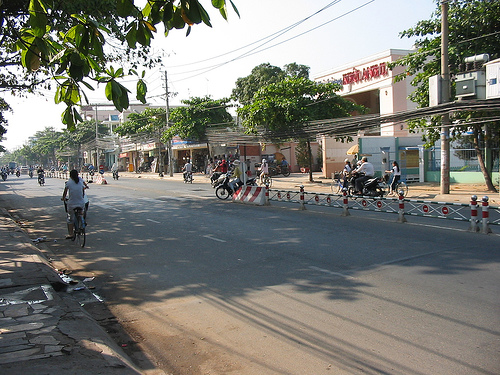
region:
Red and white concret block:
[235, 186, 266, 203]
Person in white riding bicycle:
[62, 169, 90, 241]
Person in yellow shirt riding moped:
[217, 159, 243, 199]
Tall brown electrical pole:
[440, 5, 451, 192]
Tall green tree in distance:
[31, 126, 59, 158]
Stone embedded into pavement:
[1, 305, 62, 362]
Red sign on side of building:
[343, 63, 388, 86]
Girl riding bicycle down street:
[384, 161, 409, 196]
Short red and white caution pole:
[298, 184, 305, 214]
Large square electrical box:
[454, 73, 485, 99]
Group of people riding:
[327, 155, 412, 197]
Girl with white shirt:
[52, 168, 102, 247]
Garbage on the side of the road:
[27, 230, 84, 300]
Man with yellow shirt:
[222, 162, 251, 199]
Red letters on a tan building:
[331, 54, 396, 92]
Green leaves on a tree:
[7, 52, 158, 136]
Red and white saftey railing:
[267, 188, 498, 231]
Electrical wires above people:
[210, 119, 474, 143]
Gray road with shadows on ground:
[105, 195, 499, 367]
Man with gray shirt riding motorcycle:
[177, 157, 202, 192]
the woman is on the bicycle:
[53, 166, 108, 246]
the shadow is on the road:
[162, 238, 196, 291]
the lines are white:
[132, 210, 228, 250]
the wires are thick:
[200, 32, 305, 57]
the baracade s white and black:
[225, 185, 360, 213]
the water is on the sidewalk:
[15, 277, 55, 305]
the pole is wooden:
[437, 6, 453, 66]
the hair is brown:
[70, 173, 82, 185]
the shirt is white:
[67, 183, 87, 206]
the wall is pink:
[389, 86, 406, 111]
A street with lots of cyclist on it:
[56, 142, 437, 316]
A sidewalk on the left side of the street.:
[5, 242, 108, 355]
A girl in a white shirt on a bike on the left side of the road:
[57, 169, 114, 238]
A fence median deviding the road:
[283, 184, 489, 219]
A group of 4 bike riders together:
[319, 156, 415, 184]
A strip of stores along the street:
[71, 121, 339, 169]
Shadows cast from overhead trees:
[60, 221, 422, 290]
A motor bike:
[218, 162, 268, 199]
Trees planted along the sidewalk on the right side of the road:
[26, 93, 486, 168]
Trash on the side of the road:
[49, 278, 102, 296]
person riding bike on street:
[44, 159, 118, 252]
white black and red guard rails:
[366, 196, 497, 228]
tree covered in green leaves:
[240, 69, 326, 122]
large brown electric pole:
[438, 7, 460, 196]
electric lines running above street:
[246, 4, 397, 48]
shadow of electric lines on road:
[224, 276, 469, 373]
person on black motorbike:
[214, 151, 269, 208]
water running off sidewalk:
[16, 259, 111, 319]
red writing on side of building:
[340, 56, 397, 90]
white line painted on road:
[283, 243, 385, 300]